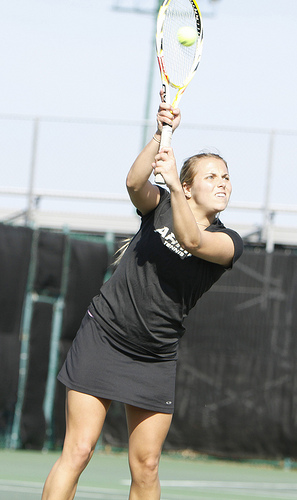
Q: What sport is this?
A: Tennis.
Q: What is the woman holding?
A: A tennis racquet.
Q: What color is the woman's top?
A: Black.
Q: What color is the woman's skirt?
A: Black.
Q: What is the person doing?
A: Playing tennis.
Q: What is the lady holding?
A: Racket.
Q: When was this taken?
A: During the day time.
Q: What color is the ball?
A: Green.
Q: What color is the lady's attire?
A: Black.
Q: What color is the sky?
A: Blue.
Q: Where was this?
A: On a tennis court.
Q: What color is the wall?
A: Black.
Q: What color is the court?
A: Green.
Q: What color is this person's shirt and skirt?
A: Black.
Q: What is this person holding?
A: A tennis racket.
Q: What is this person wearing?
A: A shirt and skirt.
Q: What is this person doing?
A: Playing tennis.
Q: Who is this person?
A: A tennis player.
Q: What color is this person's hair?
A: Blonde.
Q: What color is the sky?
A: Blue.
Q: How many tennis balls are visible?
A: One.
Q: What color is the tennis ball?
A: Neon yellow.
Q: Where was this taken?
A: Tennis court.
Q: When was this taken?
A: During a tennis match.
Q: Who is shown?
A: Tennis player.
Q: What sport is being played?
A: Tennis.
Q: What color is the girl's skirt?
A: Black.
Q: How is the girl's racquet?
A: Upright.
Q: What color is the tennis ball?
A: Yellow.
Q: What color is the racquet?
A: White.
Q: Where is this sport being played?
A: Tennis court.